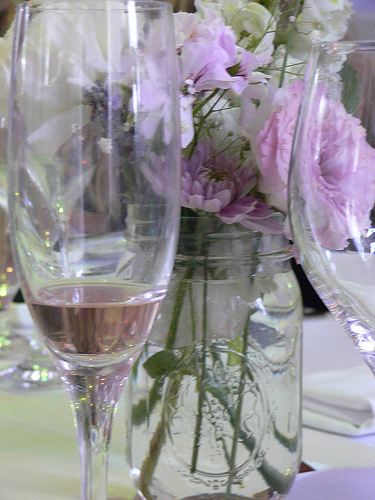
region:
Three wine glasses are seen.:
[3, 303, 369, 423]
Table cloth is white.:
[13, 415, 56, 477]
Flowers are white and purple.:
[187, 38, 292, 167]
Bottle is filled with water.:
[186, 225, 287, 461]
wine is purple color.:
[30, 274, 150, 367]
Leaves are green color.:
[153, 343, 207, 385]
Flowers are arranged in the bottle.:
[189, 141, 270, 328]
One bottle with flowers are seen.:
[159, 311, 312, 461]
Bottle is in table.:
[151, 378, 319, 483]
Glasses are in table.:
[5, 350, 370, 474]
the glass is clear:
[4, 1, 193, 496]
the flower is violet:
[193, 24, 255, 109]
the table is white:
[10, 429, 72, 489]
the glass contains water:
[15, 203, 161, 450]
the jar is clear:
[122, 207, 311, 479]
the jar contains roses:
[127, 0, 313, 490]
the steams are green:
[182, 221, 261, 482]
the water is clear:
[3, 260, 170, 462]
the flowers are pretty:
[189, 22, 372, 258]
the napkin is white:
[298, 357, 368, 438]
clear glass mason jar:
[90, 180, 327, 499]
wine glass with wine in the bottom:
[0, 0, 183, 498]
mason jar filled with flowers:
[105, 0, 335, 495]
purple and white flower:
[256, 67, 369, 255]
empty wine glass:
[288, 33, 373, 401]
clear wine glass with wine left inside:
[2, 2, 184, 493]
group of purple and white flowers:
[80, 0, 324, 251]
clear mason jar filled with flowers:
[105, 200, 316, 493]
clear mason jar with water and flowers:
[111, 200, 327, 499]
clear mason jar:
[84, 191, 319, 499]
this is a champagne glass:
[24, 220, 146, 484]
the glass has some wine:
[36, 289, 143, 352]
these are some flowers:
[185, 2, 290, 215]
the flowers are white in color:
[227, 4, 342, 26]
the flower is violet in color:
[185, 162, 248, 213]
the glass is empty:
[335, 110, 373, 325]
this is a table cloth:
[12, 406, 55, 482]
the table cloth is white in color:
[10, 420, 57, 484]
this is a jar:
[194, 212, 249, 498]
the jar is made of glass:
[271, 377, 292, 469]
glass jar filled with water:
[123, 184, 320, 494]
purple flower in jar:
[260, 80, 357, 245]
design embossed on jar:
[156, 327, 283, 490]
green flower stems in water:
[145, 284, 263, 462]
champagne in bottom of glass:
[21, 271, 172, 364]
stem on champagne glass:
[63, 345, 142, 494]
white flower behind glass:
[14, 11, 115, 155]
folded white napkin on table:
[299, 366, 371, 439]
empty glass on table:
[278, 44, 371, 359]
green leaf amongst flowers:
[334, 58, 364, 114]